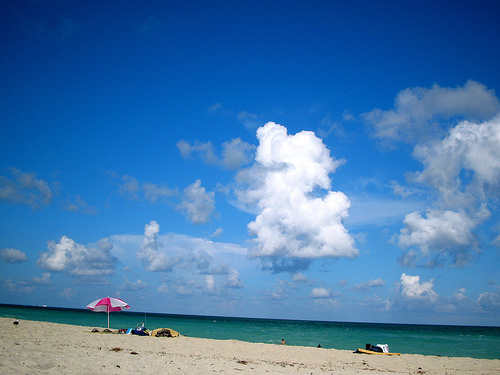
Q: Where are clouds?
A: In the sky.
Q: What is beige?
A: Sand.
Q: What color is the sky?
A: Blue.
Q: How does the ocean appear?
A: Calm.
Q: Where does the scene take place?
A: At the beach.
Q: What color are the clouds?
A: White.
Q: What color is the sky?
A: Blue.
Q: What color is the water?
A: Green.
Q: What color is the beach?
A: Brown.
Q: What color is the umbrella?
A: White and red.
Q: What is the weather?
A: Cloudy.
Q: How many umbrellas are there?
A: One.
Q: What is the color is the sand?
A: Brown.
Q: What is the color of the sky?
A: Blue.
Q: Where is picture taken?
A: Beach.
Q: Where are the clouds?
A: Sky.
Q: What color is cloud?
A: White.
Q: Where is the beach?
A: Near ocean.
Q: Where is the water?
A: Ocean.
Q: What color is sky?
A: Blue.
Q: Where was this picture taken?
A: The beach.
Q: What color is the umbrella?
A: Pink and white.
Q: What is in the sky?
A: Clouds.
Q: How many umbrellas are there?
A: One.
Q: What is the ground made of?
A: Sand.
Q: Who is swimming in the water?
A: A person.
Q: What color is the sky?
A: Blue.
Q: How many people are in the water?
A: 1.